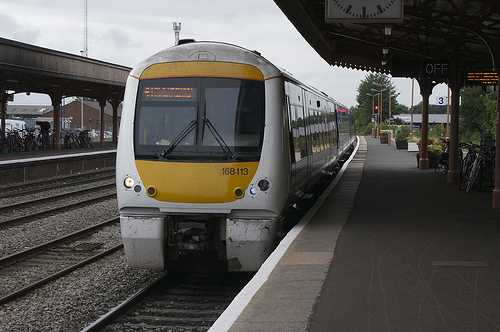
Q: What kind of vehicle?
A: Train.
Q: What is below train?
A: Tracks.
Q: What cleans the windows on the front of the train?
A: Window wipers.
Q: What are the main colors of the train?
A: White and yellow.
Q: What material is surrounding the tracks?
A: Gravel.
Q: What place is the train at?
A: Train station.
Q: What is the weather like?
A: Overcast.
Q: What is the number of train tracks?
A: Three.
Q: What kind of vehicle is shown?
A: Train.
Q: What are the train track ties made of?
A: Wood.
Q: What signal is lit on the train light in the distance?
A: Red.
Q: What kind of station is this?
A: Train station.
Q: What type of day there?
A: It's a grey cloudy day.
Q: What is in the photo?
A: A train.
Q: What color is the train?
A: White.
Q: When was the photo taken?
A: Daytime.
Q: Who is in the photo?
A: No one.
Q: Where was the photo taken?
A: Train depot.